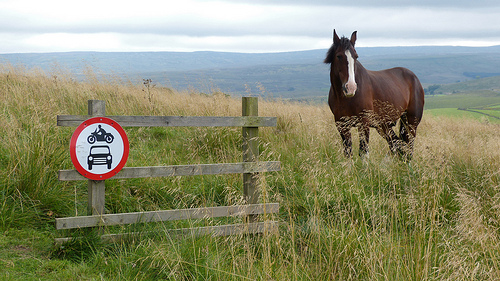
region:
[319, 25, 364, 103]
the head of a horse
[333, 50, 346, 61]
the eye of a horse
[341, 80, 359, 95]
the nose of a horse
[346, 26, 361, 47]
the ear of a horse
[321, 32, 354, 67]
the mane of a horse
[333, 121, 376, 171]
the front legs of a horse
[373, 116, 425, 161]
the rear legs of a horse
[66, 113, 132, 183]
a red, white, and black sign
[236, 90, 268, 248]
a brown wooden fence post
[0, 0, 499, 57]
a cloudy gray sky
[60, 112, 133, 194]
round sign on a fence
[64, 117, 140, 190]
sign with a red border on the fence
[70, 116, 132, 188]
sign with a picture of a bike and a car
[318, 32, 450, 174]
a horse standing in the grass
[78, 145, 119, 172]
a picture of a car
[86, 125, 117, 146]
a picture of a motorbike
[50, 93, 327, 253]
a wooden fence with a round sign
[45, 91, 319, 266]
a wooden fence in the grass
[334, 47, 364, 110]
white stripe on the horses nose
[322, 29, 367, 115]
horses head turned to its left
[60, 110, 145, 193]
THE SIGN IS ROUND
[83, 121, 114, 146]
THE SIGN HAS A MOTORCYCLE ON IT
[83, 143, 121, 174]
THE SIGN HAS A CAR ON IT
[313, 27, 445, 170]
THE HORSE IS BROWN AND WHITE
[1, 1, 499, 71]
THE SKY IS VERY CLOUDY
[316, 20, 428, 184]
THE HORSE IS STANDING IN THE TALL GRASS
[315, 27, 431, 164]
THE HORSE IS STANDING IN THE DRY GRASS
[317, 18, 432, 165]
THE HORSE IS STANDING IN THE BROWN GRASS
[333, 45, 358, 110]
THE HORSE HAS A WHITE FACE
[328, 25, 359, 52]
THESE ARE THE HORSES EARS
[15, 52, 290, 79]
hills in the background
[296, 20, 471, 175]
the horse in the grass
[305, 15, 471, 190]
the horse is brown and white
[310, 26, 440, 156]
the horse is standing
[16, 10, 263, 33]
gray clouds in the sky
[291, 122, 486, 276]
the grass is tall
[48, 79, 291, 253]
the fence post beside the horse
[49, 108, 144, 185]
the sign on the fence post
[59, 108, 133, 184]
the sign is red black and white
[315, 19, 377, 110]
the head of the horse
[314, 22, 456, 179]
Horse in tall grass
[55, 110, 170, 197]
Red and white sign on post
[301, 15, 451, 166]
brown and white horse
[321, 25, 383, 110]
Brown horse with white nose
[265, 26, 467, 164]
Brown horse by sign on post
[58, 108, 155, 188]
Sign with motorcycle and car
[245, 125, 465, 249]
Green grass in a field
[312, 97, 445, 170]
Horse has four legs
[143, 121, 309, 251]
Wooded post for a sign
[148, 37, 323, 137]
Rolling hills in the background